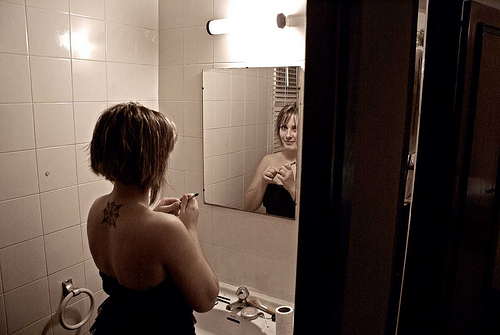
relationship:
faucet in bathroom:
[226, 287, 253, 313] [3, 1, 488, 328]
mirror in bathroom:
[197, 60, 300, 226] [8, 6, 335, 327]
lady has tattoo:
[96, 101, 201, 333] [97, 197, 125, 230]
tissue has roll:
[272, 306, 297, 335] [272, 303, 298, 332]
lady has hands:
[96, 101, 201, 333] [155, 191, 212, 222]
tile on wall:
[30, 104, 77, 145] [0, 0, 200, 320]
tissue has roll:
[272, 306, 297, 335] [273, 302, 293, 331]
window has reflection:
[267, 66, 299, 156] [244, 70, 301, 219]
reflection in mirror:
[244, 70, 301, 219] [199, 66, 297, 220]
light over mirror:
[186, 9, 303, 44] [190, 60, 327, 243]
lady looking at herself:
[96, 101, 201, 333] [239, 98, 299, 218]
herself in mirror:
[239, 98, 299, 218] [197, 63, 309, 224]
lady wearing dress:
[96, 101, 201, 333] [88, 265, 197, 334]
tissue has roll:
[273, 303, 296, 331] [274, 305, 294, 333]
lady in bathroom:
[58, 80, 203, 332] [6, 9, 405, 333]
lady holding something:
[96, 101, 201, 333] [181, 191, 199, 206]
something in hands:
[181, 191, 199, 206] [264, 164, 296, 186]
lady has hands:
[96, 101, 201, 333] [264, 164, 296, 186]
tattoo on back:
[102, 200, 121, 227] [87, 192, 167, 287]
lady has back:
[96, 101, 201, 333] [87, 192, 167, 287]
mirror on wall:
[197, 60, 300, 226] [167, 28, 300, 253]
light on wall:
[204, 19, 235, 36] [160, 0, 297, 302]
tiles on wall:
[45, 27, 130, 105] [8, 11, 153, 303]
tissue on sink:
[272, 306, 297, 335] [163, 280, 294, 333]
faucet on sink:
[226, 287, 253, 313] [195, 279, 291, 331]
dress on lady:
[94, 267, 197, 331] [96, 101, 201, 333]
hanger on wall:
[56, 286, 97, 329] [0, 0, 165, 334]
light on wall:
[204, 19, 235, 36] [106, 12, 346, 235]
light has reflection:
[204, 19, 235, 36] [51, 16, 107, 61]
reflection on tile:
[51, 16, 107, 61] [7, 0, 156, 332]